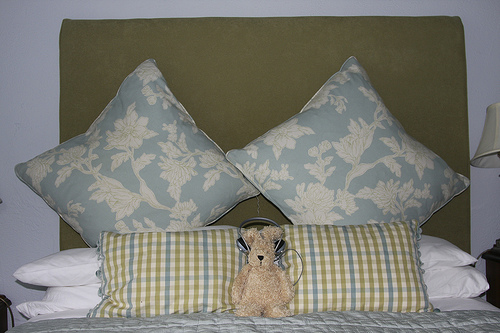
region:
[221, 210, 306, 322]
Teddy bear wearing a pair of headphones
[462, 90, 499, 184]
Side of a lampshade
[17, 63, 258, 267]
Blue and white floral pillow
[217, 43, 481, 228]
Blue and white floral pillow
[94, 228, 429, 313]
Blue and yellow checkered pillow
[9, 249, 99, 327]
Stack of white pillows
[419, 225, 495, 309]
Stack of white pillows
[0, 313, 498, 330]
Top edge of the light gray bedspread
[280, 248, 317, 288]
Black headphone cord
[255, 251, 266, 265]
Bear's brown nose and mouth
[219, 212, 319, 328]
Stuffed rabbit wearing headphones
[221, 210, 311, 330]
Stuffed rabbit sitting on bed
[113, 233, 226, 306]
Blue, green, and white plaid pillow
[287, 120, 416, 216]
Blue pillow with white floral design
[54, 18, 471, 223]
Square throw pillows standing against green headboard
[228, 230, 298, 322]
Light brown stuffed rabbit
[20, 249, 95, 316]
Stacked white pillows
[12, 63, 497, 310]
Grouping of eight pillows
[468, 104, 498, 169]
Lamp with beige lamp shade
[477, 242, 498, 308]
Brown end table beside bed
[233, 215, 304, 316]
a stuffed rabbit sitting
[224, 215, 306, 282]
the rabbit is wearing headphones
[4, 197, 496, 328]
the rabbit sitting on the bed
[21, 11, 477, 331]
pillows leaning on a headboard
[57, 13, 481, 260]
the headboard is brown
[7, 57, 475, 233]
two pillows turned sideways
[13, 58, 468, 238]
the pillows are blue and white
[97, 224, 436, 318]
these pillows are checked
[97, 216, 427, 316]
the pillows are blue and yellow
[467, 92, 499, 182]
a lamp beside the bed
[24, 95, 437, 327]
Stack of pillows on bed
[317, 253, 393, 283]
Plaid on the pillow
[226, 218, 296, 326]
Stuffed animal on the bed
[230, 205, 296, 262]
Headphones on the stuffed animal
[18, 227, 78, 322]
White pillows stacked on the bed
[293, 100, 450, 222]
Pillow with floral design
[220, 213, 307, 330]
The stuffed animal is a rabbit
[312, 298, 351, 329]
The bed is made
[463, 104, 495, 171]
Lamp sitting on a table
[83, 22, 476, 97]
The headboard behind the pillows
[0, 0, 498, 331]
A bed next to a wall.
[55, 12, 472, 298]
The headboard is brown.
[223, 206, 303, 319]
A stuffed bear is sitting on the bed.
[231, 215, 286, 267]
The bear is wearing head phones.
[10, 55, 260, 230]
The pillow on the left is blue with white flowers.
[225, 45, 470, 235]
The pillow on the right is blue with white flowers.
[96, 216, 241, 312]
The pillow on the left is white with yellow and blue stripes.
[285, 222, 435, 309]
The pillow on the right is white with blue and yellow stripes.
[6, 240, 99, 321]
A stack of white pillows on the left side of the bed.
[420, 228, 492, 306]
A stack of white pillows on the right side of the bed.